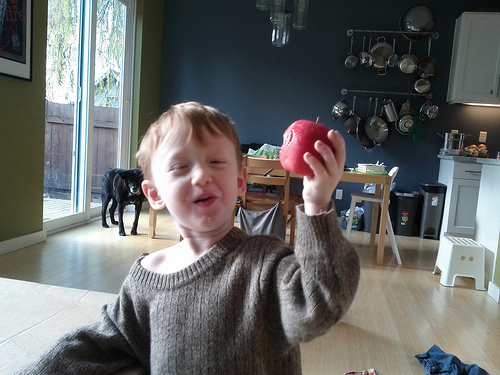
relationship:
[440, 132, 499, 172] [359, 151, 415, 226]
oranges on table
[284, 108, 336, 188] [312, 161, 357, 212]
apple in hand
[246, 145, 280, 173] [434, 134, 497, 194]
fruits on counter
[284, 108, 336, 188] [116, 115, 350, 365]
apple with boy